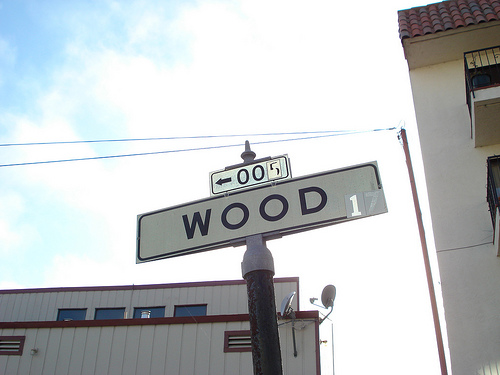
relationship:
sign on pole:
[133, 139, 387, 264] [241, 234, 286, 373]